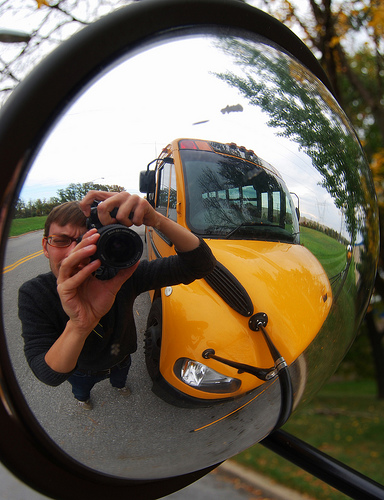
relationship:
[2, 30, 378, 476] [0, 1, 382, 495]
reflection in mirror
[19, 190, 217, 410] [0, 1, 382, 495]
man in mirror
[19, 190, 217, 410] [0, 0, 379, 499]
man in picture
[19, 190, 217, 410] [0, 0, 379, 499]
man taking picture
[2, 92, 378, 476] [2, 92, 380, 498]
reflection in mirror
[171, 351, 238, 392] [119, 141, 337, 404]
headlight on bus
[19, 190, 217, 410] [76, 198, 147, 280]
man has camera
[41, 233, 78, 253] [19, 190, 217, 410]
glasses on man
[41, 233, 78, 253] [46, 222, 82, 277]
glasses on face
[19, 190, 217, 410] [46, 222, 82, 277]
man has face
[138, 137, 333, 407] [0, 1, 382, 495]
bus in mirror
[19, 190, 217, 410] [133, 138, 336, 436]
man taking picture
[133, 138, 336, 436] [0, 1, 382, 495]
picture of mirror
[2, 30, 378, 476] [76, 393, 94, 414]
reflection of shoe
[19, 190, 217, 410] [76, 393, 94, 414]
man has shoe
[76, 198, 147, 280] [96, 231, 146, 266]
camera has lens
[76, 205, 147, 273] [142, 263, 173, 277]
camera lens black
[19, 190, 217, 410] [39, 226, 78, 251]
man wears glasses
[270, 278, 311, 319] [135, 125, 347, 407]
yellow school bus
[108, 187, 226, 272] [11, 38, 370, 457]
arm supporting mirror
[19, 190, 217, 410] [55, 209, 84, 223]
man has brown hair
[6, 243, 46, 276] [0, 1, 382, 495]
road in mirror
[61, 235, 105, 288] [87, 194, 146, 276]
fingers holding camera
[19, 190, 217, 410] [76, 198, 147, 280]
man into camera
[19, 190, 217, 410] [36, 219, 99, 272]
man has a camera by h face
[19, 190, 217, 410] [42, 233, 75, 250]
man wearing glasses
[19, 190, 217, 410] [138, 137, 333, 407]
man next to school bus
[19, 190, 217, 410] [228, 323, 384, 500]
man in green green grass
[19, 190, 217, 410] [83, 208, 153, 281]
man focusing camera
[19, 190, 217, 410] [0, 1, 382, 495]
man taking picture of side view mirror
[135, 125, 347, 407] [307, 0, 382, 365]
bus parked next to tree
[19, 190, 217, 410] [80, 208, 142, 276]
man holding camera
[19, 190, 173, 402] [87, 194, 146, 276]
man with glasses and a camera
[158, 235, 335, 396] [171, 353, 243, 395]
yellow vehicle with headlight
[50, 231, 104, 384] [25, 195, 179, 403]
hand of man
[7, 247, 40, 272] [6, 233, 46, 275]
yellow line on road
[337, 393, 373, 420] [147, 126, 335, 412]
green grass next to bus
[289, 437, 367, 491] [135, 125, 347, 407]
black pole on bus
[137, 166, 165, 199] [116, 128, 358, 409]
mirror on bus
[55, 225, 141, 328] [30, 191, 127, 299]
hand of a man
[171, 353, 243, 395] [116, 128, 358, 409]
headlight of a bus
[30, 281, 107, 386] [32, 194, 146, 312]
arm of man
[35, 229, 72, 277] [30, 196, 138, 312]
ear of man